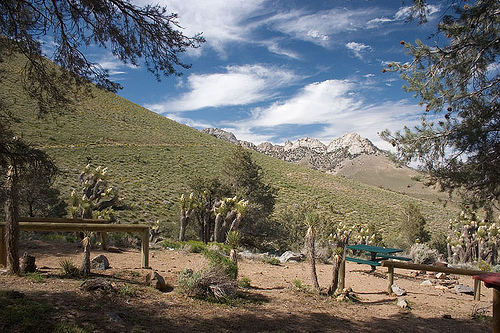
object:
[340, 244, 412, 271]
bench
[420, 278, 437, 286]
rocks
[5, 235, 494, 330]
ground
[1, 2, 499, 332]
deset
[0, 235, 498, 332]
soil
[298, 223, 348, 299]
trunks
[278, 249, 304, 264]
rock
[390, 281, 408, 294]
rock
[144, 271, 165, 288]
rock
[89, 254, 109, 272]
rock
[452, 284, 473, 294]
rock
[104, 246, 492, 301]
sand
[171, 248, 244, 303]
bush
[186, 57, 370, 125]
clouds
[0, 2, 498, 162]
sky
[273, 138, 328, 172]
mountain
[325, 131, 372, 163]
mountain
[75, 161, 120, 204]
cactus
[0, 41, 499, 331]
desert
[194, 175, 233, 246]
tree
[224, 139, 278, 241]
tree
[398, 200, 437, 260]
tree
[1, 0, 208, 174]
tree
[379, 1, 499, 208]
tree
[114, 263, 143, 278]
rock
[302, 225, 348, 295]
cacti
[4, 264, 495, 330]
shadows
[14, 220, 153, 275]
wooden post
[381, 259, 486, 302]
wooden post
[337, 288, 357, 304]
rocks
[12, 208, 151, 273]
post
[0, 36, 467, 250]
hillside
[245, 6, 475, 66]
clouds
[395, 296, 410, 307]
rock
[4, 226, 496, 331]
dirt